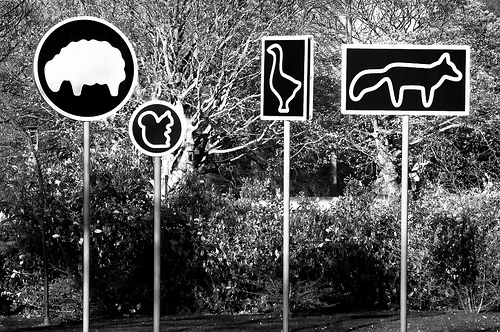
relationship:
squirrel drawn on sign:
[136, 105, 175, 147] [125, 91, 187, 330]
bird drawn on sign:
[266, 42, 303, 114] [250, 19, 320, 149]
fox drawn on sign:
[353, 50, 462, 106] [332, 25, 470, 129]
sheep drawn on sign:
[31, 36, 133, 101] [27, 11, 137, 126]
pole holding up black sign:
[82, 116, 88, 330] [32, 15, 139, 122]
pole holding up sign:
[111, 184, 191, 291] [111, 62, 207, 184]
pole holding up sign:
[395, 112, 419, 329] [343, 40, 472, 119]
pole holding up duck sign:
[278, 114, 293, 330] [260, 34, 314, 121]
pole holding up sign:
[153, 158, 162, 291] [127, 99, 189, 159]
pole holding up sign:
[82, 116, 92, 330] [27, 11, 137, 126]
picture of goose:
[258, 34, 304, 122] [244, 17, 337, 225]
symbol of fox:
[338, 15, 484, 176] [348, 43, 493, 157]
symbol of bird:
[244, 17, 325, 205] [260, 22, 309, 125]